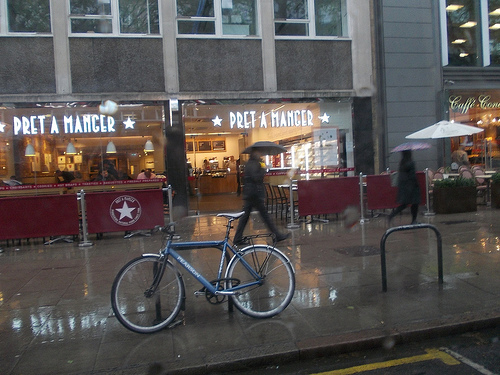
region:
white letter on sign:
[12, 116, 23, 136]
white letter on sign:
[19, 114, 31, 136]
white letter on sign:
[26, 115, 39, 135]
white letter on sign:
[35, 114, 47, 132]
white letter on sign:
[50, 116, 60, 133]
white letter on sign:
[61, 115, 75, 133]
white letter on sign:
[72, 115, 82, 135]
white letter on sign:
[81, 113, 91, 134]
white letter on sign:
[89, 113, 99, 132]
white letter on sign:
[98, 111, 108, 132]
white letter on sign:
[46, 113, 62, 135]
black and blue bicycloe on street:
[112, 209, 295, 334]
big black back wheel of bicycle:
[221, 244, 297, 322]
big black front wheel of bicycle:
[111, 250, 185, 335]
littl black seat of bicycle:
[217, 207, 244, 222]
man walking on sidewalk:
[234, 147, 290, 249]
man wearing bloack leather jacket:
[234, 149, 294, 246]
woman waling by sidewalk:
[387, 149, 422, 220]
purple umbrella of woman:
[390, 137, 431, 154]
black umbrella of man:
[240, 140, 285, 155]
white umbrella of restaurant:
[404, 112, 484, 143]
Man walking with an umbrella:
[229, 140, 291, 246]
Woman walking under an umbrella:
[384, 137, 430, 227]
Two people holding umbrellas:
[226, 138, 432, 244]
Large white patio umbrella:
[402, 118, 484, 171]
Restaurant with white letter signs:
[0, 83, 377, 216]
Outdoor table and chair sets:
[249, 160, 499, 223]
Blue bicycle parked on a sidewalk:
[107, 210, 295, 335]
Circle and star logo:
[106, 193, 143, 228]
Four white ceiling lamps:
[21, 140, 155, 157]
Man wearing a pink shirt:
[136, 167, 156, 182]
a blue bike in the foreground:
[100, 182, 300, 331]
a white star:
[113, 200, 136, 222]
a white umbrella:
[402, 120, 484, 140]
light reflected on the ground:
[24, 300, 109, 334]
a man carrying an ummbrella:
[235, 143, 292, 246]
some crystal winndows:
[5, 2, 347, 37]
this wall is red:
[7, 202, 83, 237]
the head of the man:
[247, 148, 264, 157]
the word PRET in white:
[12, 116, 47, 133]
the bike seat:
[217, 208, 244, 220]